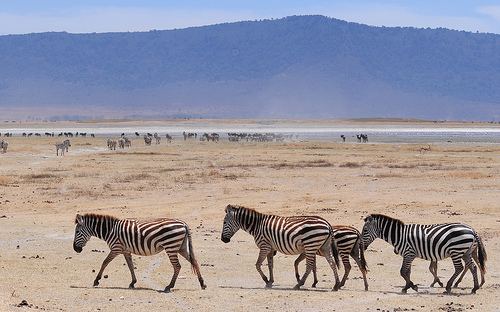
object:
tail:
[184, 226, 198, 274]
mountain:
[0, 15, 499, 121]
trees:
[475, 29, 480, 33]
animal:
[3, 132, 13, 138]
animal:
[133, 132, 140, 136]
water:
[0, 132, 499, 136]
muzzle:
[73, 241, 85, 252]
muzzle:
[220, 236, 232, 243]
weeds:
[0, 176, 17, 183]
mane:
[80, 212, 119, 221]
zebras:
[220, 204, 343, 291]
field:
[0, 136, 499, 311]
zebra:
[72, 212, 207, 293]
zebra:
[358, 213, 487, 294]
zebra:
[53, 139, 72, 156]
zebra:
[105, 137, 115, 147]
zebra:
[118, 139, 127, 148]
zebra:
[163, 133, 173, 143]